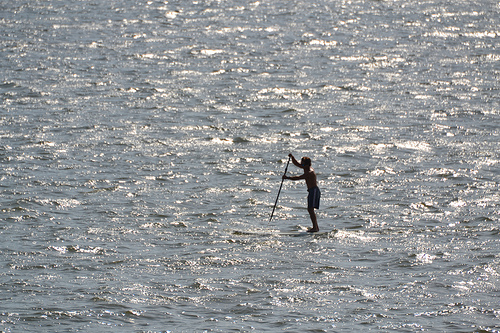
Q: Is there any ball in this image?
A: No, there are no balls.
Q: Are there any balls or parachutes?
A: No, there are no balls or parachutes.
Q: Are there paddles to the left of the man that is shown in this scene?
A: Yes, there is a paddle to the left of the man.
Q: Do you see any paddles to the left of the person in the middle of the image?
A: Yes, there is a paddle to the left of the man.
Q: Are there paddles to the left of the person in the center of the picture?
A: Yes, there is a paddle to the left of the man.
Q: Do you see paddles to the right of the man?
A: No, the paddle is to the left of the man.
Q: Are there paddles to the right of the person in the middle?
A: No, the paddle is to the left of the man.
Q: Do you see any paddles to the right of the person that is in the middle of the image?
A: No, the paddle is to the left of the man.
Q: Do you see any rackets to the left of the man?
A: No, there is a paddle to the left of the man.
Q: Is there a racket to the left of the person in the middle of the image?
A: No, there is a paddle to the left of the man.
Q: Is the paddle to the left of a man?
A: Yes, the paddle is to the left of a man.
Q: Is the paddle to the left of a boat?
A: No, the paddle is to the left of a man.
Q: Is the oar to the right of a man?
A: No, the oar is to the left of a man.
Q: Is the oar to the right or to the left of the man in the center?
A: The oar is to the left of the man.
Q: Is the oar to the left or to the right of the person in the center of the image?
A: The oar is to the left of the man.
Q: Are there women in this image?
A: No, there are no women.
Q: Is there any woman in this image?
A: No, there are no women.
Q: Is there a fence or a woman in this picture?
A: No, there are no women or fences.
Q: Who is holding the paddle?
A: The man is holding the paddle.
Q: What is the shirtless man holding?
A: The man is holding the oar.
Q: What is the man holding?
A: The man is holding the oar.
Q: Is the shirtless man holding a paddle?
A: Yes, the man is holding a paddle.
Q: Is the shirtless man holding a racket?
A: No, the man is holding a paddle.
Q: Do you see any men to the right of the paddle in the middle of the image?
A: Yes, there is a man to the right of the paddle.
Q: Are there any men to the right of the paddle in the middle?
A: Yes, there is a man to the right of the paddle.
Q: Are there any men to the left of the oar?
A: No, the man is to the right of the oar.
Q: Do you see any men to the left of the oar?
A: No, the man is to the right of the oar.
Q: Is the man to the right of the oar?
A: Yes, the man is to the right of the oar.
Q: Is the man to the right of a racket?
A: No, the man is to the right of the oar.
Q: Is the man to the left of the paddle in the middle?
A: No, the man is to the right of the oar.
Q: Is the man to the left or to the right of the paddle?
A: The man is to the right of the paddle.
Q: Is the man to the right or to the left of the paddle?
A: The man is to the right of the paddle.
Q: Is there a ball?
A: No, there are no balls.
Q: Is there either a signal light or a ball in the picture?
A: No, there are no balls or traffic lights.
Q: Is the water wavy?
A: Yes, the water is wavy.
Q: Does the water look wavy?
A: Yes, the water is wavy.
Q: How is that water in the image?
A: The water is wavy.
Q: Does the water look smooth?
A: No, the water is wavy.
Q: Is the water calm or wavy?
A: The water is wavy.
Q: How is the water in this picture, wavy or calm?
A: The water is wavy.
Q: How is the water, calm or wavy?
A: The water is wavy.